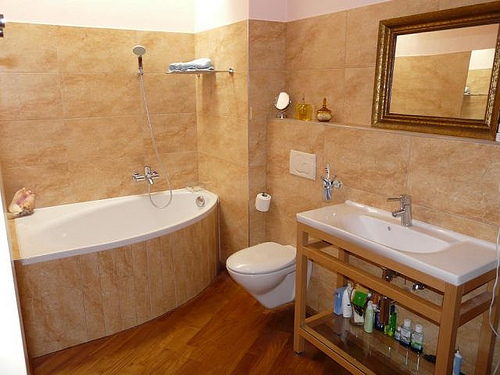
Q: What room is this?
A: Bathroom.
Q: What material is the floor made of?
A: Wood.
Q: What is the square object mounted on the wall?
A: Mirror.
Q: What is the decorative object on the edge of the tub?
A: Sea shell.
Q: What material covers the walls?
A: Tile.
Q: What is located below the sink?
A: Bottles.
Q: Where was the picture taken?
A: In a bathroom.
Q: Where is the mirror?
A: Above the sink.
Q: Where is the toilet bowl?
A: Between the sink and bathtub.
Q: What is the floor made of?
A: Wood.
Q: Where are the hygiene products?
A: Under the sink.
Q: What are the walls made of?
A: Tiles.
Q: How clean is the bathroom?
A: Very clean.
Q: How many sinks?
A: One.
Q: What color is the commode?
A: White.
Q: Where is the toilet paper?
A: Next to the commode.